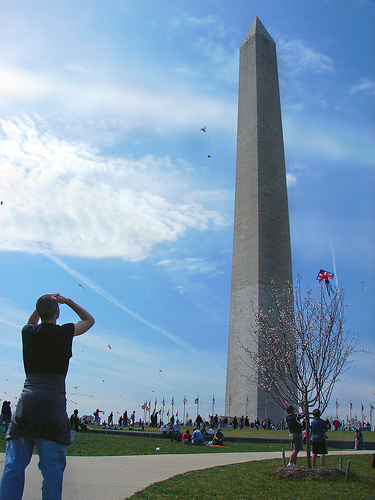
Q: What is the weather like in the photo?
A: It is clear.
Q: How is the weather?
A: It is clear.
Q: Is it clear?
A: Yes, it is clear.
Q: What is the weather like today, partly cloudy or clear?
A: It is clear.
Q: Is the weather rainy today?
A: No, it is clear.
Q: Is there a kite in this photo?
A: Yes, there is a kite.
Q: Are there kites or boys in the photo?
A: Yes, there is a kite.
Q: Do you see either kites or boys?
A: Yes, there is a kite.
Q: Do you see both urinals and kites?
A: No, there is a kite but no urinals.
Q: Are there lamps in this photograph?
A: No, there are no lamps.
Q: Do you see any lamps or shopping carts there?
A: No, there are no lamps or shopping carts.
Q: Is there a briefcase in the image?
A: No, there are no briefcases.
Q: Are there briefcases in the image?
A: No, there are no briefcases.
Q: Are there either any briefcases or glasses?
A: No, there are no briefcases or glasses.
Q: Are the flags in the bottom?
A: Yes, the flags are in the bottom of the image.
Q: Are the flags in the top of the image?
A: No, the flags are in the bottom of the image.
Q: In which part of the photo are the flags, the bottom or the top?
A: The flags are in the bottom of the image.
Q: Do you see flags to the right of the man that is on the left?
A: Yes, there are flags to the right of the man.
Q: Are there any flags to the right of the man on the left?
A: Yes, there are flags to the right of the man.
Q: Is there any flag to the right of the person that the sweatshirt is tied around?
A: Yes, there are flags to the right of the man.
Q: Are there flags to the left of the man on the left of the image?
A: No, the flags are to the right of the man.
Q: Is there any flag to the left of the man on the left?
A: No, the flags are to the right of the man.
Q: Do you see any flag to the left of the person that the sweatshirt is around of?
A: No, the flags are to the right of the man.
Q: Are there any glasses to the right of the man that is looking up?
A: No, there are flags to the right of the man.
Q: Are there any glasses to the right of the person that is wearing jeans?
A: No, there are flags to the right of the man.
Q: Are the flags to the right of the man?
A: Yes, the flags are to the right of the man.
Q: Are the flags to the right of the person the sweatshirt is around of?
A: Yes, the flags are to the right of the man.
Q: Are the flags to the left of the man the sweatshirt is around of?
A: No, the flags are to the right of the man.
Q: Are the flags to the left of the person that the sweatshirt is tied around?
A: No, the flags are to the right of the man.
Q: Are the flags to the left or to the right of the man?
A: The flags are to the right of the man.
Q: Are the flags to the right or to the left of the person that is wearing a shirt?
A: The flags are to the right of the man.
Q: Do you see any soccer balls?
A: No, there are no soccer balls.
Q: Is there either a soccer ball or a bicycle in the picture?
A: No, there are no soccer balls or bicycles.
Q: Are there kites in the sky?
A: Yes, there are kites in the sky.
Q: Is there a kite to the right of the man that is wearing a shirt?
A: Yes, there are kites to the right of the man.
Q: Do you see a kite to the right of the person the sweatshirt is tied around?
A: Yes, there are kites to the right of the man.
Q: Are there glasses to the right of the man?
A: No, there are kites to the right of the man.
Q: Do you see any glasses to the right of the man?
A: No, there are kites to the right of the man.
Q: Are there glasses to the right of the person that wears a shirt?
A: No, there are kites to the right of the man.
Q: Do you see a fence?
A: No, there are no fences.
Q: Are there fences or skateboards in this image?
A: No, there are no fences or skateboards.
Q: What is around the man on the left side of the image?
A: The sweatshirt is around the man.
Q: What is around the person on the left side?
A: The sweatshirt is around the man.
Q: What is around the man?
A: The sweatshirt is around the man.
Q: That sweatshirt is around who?
A: The sweatshirt is around the man.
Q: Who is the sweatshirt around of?
A: The sweatshirt is around the man.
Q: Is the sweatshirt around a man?
A: Yes, the sweatshirt is around a man.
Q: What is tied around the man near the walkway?
A: The sweatshirt is tied around the man.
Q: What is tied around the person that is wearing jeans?
A: The sweatshirt is tied around the man.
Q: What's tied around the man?
A: The sweatshirt is tied around the man.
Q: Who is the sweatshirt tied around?
A: The sweatshirt is tied around the man.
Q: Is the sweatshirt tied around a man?
A: Yes, the sweatshirt is tied around a man.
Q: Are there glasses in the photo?
A: No, there are no glasses.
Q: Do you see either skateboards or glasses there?
A: No, there are no glasses or skateboards.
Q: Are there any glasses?
A: No, there are no glasses.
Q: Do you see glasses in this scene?
A: No, there are no glasses.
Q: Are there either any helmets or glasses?
A: No, there are no glasses or helmets.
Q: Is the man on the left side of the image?
A: Yes, the man is on the left of the image.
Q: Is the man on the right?
A: No, the man is on the left of the image.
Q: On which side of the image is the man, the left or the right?
A: The man is on the left of the image.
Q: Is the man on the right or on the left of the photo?
A: The man is on the left of the image.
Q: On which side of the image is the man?
A: The man is on the left of the image.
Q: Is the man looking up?
A: Yes, the man is looking up.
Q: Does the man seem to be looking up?
A: Yes, the man is looking up.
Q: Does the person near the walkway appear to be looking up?
A: Yes, the man is looking up.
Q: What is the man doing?
A: The man is looking up.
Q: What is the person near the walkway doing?
A: The man is looking up.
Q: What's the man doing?
A: The man is looking up.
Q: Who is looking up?
A: The man is looking up.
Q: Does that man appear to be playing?
A: No, the man is looking up.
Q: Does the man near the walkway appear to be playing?
A: No, the man is looking up.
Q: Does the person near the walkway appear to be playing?
A: No, the man is looking up.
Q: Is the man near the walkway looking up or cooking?
A: The man is looking up.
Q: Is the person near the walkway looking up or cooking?
A: The man is looking up.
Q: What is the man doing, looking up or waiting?
A: The man is looking up.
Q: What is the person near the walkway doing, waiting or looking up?
A: The man is looking up.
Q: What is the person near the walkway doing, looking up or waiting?
A: The man is looking up.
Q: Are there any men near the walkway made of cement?
A: Yes, there is a man near the walkway.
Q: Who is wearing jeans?
A: The man is wearing jeans.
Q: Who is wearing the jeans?
A: The man is wearing jeans.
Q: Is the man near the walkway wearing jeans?
A: Yes, the man is wearing jeans.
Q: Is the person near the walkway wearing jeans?
A: Yes, the man is wearing jeans.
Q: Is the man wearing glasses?
A: No, the man is wearing jeans.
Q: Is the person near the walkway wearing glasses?
A: No, the man is wearing jeans.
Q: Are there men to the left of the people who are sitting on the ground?
A: Yes, there is a man to the left of the people.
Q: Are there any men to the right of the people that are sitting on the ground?
A: No, the man is to the left of the people.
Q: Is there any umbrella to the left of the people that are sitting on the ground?
A: No, there is a man to the left of the people.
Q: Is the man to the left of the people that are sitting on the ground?
A: Yes, the man is to the left of the people.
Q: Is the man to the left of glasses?
A: No, the man is to the left of the people.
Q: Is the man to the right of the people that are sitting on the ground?
A: No, the man is to the left of the people.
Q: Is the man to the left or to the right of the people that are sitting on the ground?
A: The man is to the left of the people.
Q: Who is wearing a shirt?
A: The man is wearing a shirt.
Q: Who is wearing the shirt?
A: The man is wearing a shirt.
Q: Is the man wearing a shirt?
A: Yes, the man is wearing a shirt.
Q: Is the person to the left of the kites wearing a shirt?
A: Yes, the man is wearing a shirt.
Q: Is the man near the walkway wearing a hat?
A: No, the man is wearing a shirt.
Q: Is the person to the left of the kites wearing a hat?
A: No, the man is wearing a shirt.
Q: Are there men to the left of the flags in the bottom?
A: Yes, there is a man to the left of the flags.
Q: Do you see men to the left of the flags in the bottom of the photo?
A: Yes, there is a man to the left of the flags.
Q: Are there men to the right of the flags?
A: No, the man is to the left of the flags.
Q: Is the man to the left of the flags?
A: Yes, the man is to the left of the flags.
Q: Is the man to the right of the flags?
A: No, the man is to the left of the flags.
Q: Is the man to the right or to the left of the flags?
A: The man is to the left of the flags.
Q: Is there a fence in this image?
A: No, there are no fences.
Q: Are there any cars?
A: No, there are no cars.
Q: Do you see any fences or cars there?
A: No, there are no cars or fences.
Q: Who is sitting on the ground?
A: The people are sitting on the ground.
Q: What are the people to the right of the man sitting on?
A: The people are sitting on the ground.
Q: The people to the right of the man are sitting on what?
A: The people are sitting on the ground.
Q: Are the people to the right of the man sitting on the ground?
A: Yes, the people are sitting on the ground.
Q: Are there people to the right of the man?
A: Yes, there are people to the right of the man.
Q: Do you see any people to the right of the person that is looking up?
A: Yes, there are people to the right of the man.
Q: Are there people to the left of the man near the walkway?
A: No, the people are to the right of the man.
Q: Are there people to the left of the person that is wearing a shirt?
A: No, the people are to the right of the man.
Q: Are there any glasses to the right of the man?
A: No, there are people to the right of the man.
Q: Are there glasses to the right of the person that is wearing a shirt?
A: No, there are people to the right of the man.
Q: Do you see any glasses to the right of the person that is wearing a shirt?
A: No, there are people to the right of the man.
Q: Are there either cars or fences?
A: No, there are no cars or fences.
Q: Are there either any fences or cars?
A: No, there are no cars or fences.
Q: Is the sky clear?
A: Yes, the sky is clear.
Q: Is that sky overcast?
A: No, the sky is clear.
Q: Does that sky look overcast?
A: No, the sky is clear.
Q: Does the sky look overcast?
A: No, the sky is clear.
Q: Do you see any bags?
A: No, there are no bags.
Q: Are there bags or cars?
A: No, there are no bags or cars.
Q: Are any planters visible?
A: No, there are no planters.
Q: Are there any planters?
A: No, there are no planters.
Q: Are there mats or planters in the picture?
A: No, there are no planters or mats.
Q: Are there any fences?
A: No, there are no fences.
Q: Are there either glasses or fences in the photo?
A: No, there are no fences or glasses.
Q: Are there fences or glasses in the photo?
A: No, there are no fences or glasses.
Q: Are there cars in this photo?
A: No, there are no cars.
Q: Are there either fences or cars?
A: No, there are no cars or fences.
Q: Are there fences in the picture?
A: No, there are no fences.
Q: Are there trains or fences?
A: No, there are no fences or trains.